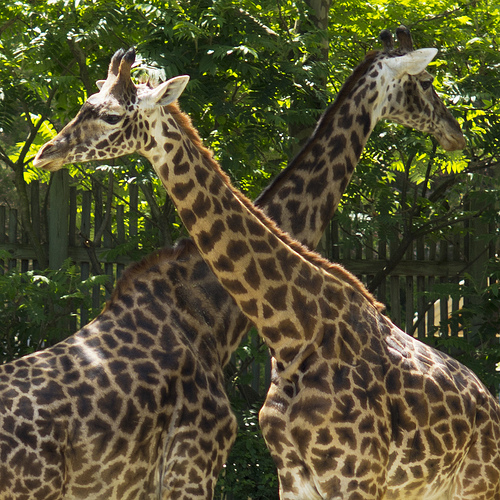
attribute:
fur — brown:
[169, 103, 388, 320]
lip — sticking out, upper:
[28, 159, 46, 170]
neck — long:
[324, 109, 355, 212]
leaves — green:
[11, 17, 66, 103]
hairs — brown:
[333, 265, 375, 296]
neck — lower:
[172, 144, 410, 346]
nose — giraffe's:
[27, 125, 89, 182]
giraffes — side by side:
[22, 25, 487, 466]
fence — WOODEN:
[316, 190, 498, 397]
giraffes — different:
[21, 38, 471, 319]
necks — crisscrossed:
[141, 129, 381, 320]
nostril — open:
[54, 135, 72, 153]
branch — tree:
[368, 231, 421, 288]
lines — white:
[326, 350, 422, 446]